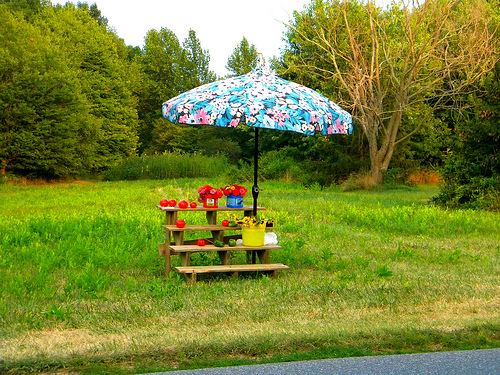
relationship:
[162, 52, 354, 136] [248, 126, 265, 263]
umbella on pole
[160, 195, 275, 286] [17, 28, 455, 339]
stand in park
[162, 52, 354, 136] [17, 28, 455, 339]
umbella in park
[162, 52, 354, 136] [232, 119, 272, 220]
umbella has pole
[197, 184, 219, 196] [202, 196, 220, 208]
red flowers in a red bucket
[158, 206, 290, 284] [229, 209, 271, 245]
stand with flowers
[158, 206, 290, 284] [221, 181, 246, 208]
stand with flowers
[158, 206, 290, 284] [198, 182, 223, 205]
stand with flowers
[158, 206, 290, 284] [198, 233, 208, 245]
stand with fruit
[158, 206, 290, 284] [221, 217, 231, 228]
stand with fruit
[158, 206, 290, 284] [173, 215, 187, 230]
stand with fruit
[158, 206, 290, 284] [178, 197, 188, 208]
stand with fruit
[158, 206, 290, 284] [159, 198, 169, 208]
stand with fruit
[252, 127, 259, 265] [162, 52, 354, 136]
pole under an umbella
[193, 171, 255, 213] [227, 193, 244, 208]
flowers in bucket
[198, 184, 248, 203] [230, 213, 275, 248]
flowers in bucket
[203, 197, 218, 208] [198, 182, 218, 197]
red bucket with red flowers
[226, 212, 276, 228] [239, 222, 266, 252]
flowers in bucket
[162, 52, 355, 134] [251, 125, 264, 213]
umbella on pole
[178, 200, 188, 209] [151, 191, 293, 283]
fruit on stand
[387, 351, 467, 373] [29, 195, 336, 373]
street next to field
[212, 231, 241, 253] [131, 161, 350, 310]
cucumbers on stand